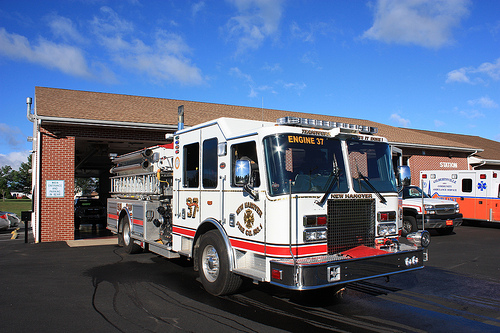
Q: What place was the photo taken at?
A: It was taken at the road.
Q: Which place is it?
A: It is a road.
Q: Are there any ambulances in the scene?
A: Yes, there is an ambulance.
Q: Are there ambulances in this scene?
A: Yes, there is an ambulance.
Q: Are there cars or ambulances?
A: Yes, there is an ambulance.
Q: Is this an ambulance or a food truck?
A: This is an ambulance.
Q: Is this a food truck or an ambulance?
A: This is an ambulance.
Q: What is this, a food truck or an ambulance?
A: This is an ambulance.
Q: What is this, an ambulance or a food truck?
A: This is an ambulance.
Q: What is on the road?
A: The ambulance is on the road.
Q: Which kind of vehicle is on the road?
A: The vehicle is an ambulance.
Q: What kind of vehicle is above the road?
A: The vehicle is an ambulance.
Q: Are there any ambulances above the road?
A: Yes, there is an ambulance above the road.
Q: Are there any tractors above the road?
A: No, there is an ambulance above the road.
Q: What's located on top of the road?
A: The ambulance is on top of the road.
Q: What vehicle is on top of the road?
A: The vehicle is an ambulance.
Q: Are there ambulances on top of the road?
A: Yes, there is an ambulance on top of the road.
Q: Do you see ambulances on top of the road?
A: Yes, there is an ambulance on top of the road.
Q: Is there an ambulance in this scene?
A: Yes, there is an ambulance.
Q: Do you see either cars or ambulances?
A: Yes, there is an ambulance.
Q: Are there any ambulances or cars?
A: Yes, there is an ambulance.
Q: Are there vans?
A: No, there are no vans.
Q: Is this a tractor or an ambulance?
A: This is an ambulance.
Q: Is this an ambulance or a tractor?
A: This is an ambulance.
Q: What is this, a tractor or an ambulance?
A: This is an ambulance.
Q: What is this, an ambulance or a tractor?
A: This is an ambulance.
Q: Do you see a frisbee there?
A: No, there are no frisbees.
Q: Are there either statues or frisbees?
A: No, there are no frisbees or statues.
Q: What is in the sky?
A: The clouds are in the sky.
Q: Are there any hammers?
A: No, there are no hammers.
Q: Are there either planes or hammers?
A: No, there are no hammers or planes.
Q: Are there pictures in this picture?
A: No, there are no pictures.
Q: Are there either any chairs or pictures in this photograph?
A: No, there are no pictures or chairs.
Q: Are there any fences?
A: No, there are no fences.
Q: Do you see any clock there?
A: No, there are no clocks.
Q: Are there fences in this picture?
A: No, there are no fences.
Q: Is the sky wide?
A: Yes, the sky is wide.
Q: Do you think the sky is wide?
A: Yes, the sky is wide.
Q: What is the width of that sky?
A: The sky is wide.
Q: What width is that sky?
A: The sky is wide.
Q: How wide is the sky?
A: The sky is wide.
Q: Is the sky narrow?
A: No, the sky is wide.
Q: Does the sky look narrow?
A: No, the sky is wide.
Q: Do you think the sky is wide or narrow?
A: The sky is wide.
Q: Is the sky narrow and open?
A: No, the sky is open but wide.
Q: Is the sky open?
A: Yes, the sky is open.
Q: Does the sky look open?
A: Yes, the sky is open.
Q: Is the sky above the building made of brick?
A: Yes, the sky is above the building.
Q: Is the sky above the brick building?
A: Yes, the sky is above the building.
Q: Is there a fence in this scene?
A: No, there are no fences.